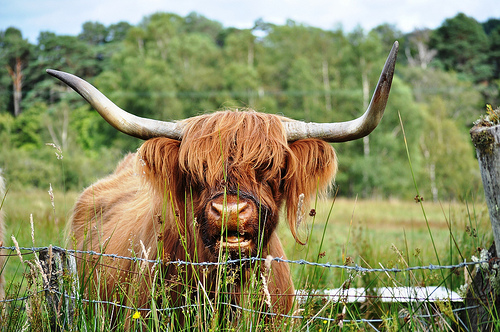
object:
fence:
[4, 240, 494, 330]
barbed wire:
[0, 242, 498, 271]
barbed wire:
[1, 285, 489, 322]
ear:
[281, 135, 338, 234]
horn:
[283, 42, 406, 145]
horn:
[42, 69, 174, 141]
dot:
[309, 208, 316, 217]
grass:
[316, 203, 421, 259]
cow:
[41, 41, 399, 332]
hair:
[135, 108, 342, 246]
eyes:
[180, 162, 219, 182]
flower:
[131, 310, 141, 319]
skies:
[216, 0, 380, 27]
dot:
[374, 73, 386, 103]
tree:
[346, 51, 391, 165]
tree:
[311, 50, 347, 127]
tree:
[235, 35, 270, 109]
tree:
[402, 37, 434, 105]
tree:
[410, 117, 450, 202]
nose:
[206, 189, 253, 223]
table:
[40, 37, 406, 253]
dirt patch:
[363, 219, 467, 231]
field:
[7, 168, 498, 330]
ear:
[146, 137, 182, 202]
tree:
[384, 74, 491, 215]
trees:
[2, 24, 47, 184]